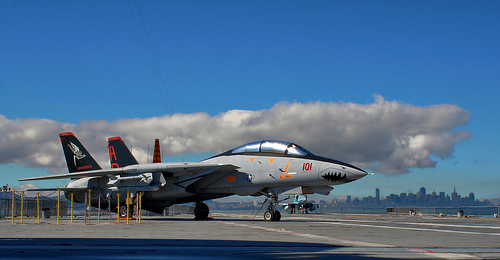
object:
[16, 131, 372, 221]
jet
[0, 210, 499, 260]
landing strip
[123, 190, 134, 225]
poles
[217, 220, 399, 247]
stripes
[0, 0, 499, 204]
sky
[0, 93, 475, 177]
cloud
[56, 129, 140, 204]
tail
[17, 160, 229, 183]
wing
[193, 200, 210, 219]
tire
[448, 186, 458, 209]
buildings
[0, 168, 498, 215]
distance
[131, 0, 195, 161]
cable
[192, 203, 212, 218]
wheel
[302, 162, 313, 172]
writing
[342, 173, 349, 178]
teeth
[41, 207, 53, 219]
trash can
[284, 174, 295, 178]
stickers